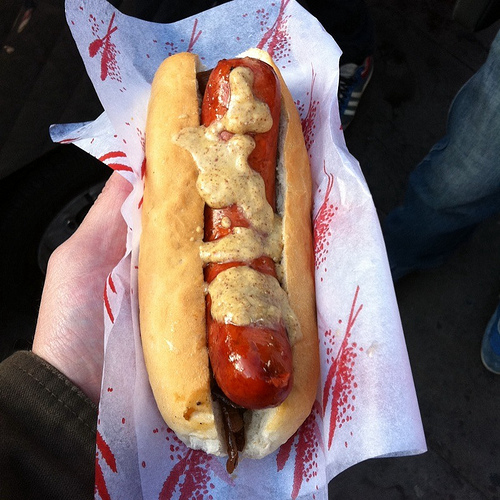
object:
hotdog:
[136, 48, 320, 475]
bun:
[136, 45, 319, 458]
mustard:
[206, 261, 304, 349]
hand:
[30, 170, 133, 407]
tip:
[263, 366, 289, 389]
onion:
[212, 390, 248, 475]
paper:
[48, 0, 428, 499]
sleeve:
[0, 347, 98, 499]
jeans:
[379, 36, 499, 287]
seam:
[10, 358, 97, 433]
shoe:
[338, 58, 374, 130]